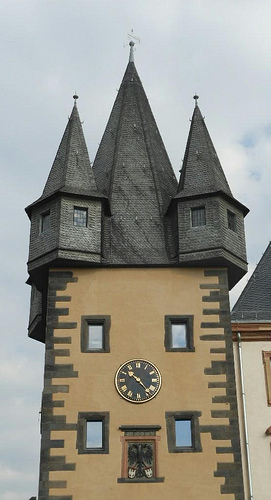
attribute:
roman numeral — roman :
[144, 386, 157, 394]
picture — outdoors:
[12, 3, 268, 492]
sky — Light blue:
[1, 1, 269, 497]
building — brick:
[55, 269, 225, 333]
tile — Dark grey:
[114, 171, 140, 216]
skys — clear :
[0, 1, 269, 498]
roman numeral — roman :
[142, 362, 148, 369]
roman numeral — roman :
[133, 359, 140, 369]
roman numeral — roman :
[142, 361, 150, 371]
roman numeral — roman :
[147, 367, 157, 376]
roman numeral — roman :
[147, 381, 157, 391]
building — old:
[1, 54, 270, 259]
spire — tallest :
[90, 28, 175, 263]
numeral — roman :
[117, 375, 125, 385]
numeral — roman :
[126, 363, 133, 372]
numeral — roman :
[125, 389, 133, 398]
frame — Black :
[76, 412, 110, 453]